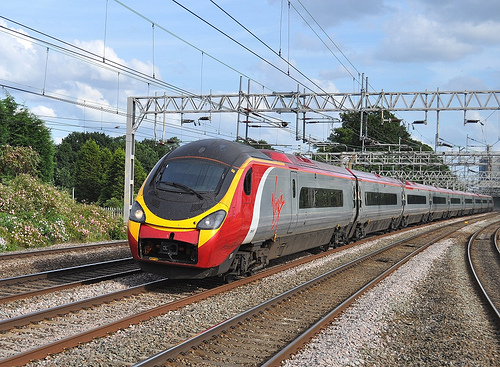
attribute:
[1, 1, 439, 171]
wires — connected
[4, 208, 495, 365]
gravel — under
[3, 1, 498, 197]
sky — blue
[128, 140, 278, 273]
front — red, yellow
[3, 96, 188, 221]
trees — green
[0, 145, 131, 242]
flowers — flowering, pink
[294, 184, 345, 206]
window — tinted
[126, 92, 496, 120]
beam — zigzagging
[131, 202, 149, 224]
headlight — shining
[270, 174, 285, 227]
writing — red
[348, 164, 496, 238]
cars — following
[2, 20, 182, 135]
cloud — fluffy, grey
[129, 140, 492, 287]
train — long, silver, passing, grey, driving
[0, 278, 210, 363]
tracks — metal